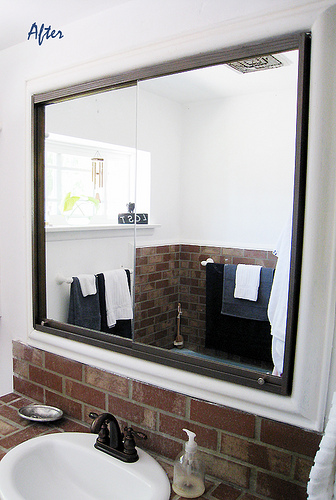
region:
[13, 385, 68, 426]
the soap dish is empty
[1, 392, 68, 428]
the soap dish is silver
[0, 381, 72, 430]
the soap dish is made of metal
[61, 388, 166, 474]
the faucet is black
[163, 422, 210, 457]
the soap dispenser top is white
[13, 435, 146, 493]
the sink is white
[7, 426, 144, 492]
the sink is clean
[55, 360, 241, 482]
brick wall under the mirror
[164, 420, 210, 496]
the soap dispenser is empty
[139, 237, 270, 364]
the mirror is reflecting a wash cloth and towel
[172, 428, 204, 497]
A bottle of soap is next to the sink.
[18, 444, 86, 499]
The sink is white.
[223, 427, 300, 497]
The wall is made of brick.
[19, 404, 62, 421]
A soap dish is next to the sink.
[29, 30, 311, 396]
A mirror is above the sink.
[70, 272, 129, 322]
Towels hang on the rack.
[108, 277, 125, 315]
The towel is white.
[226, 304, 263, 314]
The towel is blue.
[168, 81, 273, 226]
The wall is white.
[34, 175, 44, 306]
The mirror frame is dark.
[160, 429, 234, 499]
a plastic soap bottle on a counter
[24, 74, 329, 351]
a large mirror hanging on the wall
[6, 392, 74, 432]
a silver soap dish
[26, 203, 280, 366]
reflection in a mirror of a bathroom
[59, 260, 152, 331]
towels hanging on a towel rack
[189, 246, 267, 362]
three towels hanging on a towel rack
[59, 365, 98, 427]
a red brick wall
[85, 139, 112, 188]
a wind chime hanging on a window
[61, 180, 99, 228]
a small plant on a window sill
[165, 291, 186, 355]
a small statue in the corner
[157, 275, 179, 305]
reflection of red brick wall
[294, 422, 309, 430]
white framed mirror over sink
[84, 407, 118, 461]
brown faucet on white sink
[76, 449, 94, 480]
sink is white porcelain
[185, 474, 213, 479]
empty clear soap dispenser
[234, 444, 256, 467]
red brick wall under sink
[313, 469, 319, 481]
white towel hanging on wall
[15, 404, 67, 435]
stainless soap dish on sink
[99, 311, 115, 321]
reflection of blue towel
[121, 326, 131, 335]
reflection of black towel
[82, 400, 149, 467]
Faucet on a sink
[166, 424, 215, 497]
Plastic soap dispenser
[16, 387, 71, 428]
Metal soap holder on a brick counter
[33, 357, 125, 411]
Part of a brick wall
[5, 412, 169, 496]
White sink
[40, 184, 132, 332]
Mirror with a reflection of towels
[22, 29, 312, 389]
Mirror with a reflection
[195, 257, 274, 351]
Three towels hanging on a wall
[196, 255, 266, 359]
towels hanging on a brick wall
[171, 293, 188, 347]
A long brush in a corner